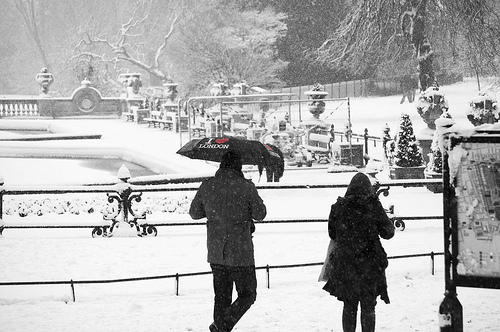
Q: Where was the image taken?
A: It was taken at the park.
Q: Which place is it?
A: It is a park.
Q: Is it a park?
A: Yes, it is a park.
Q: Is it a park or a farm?
A: It is a park.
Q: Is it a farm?
A: No, it is a park.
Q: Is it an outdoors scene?
A: Yes, it is outdoors.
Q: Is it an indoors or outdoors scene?
A: It is outdoors.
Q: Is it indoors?
A: No, it is outdoors.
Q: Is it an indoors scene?
A: No, it is outdoors.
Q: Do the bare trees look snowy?
A: Yes, the trees are snowy.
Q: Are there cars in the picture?
A: No, there are no cars.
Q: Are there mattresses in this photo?
A: No, there are no mattresses.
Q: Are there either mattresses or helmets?
A: No, there are no mattresses or helmets.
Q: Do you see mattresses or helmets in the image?
A: No, there are no mattresses or helmets.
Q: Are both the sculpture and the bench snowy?
A: Yes, both the sculpture and the bench are snowy.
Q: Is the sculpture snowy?
A: Yes, the sculpture is snowy.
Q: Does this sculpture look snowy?
A: Yes, the sculpture is snowy.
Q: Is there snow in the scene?
A: Yes, there is snow.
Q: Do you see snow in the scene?
A: Yes, there is snow.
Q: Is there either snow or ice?
A: Yes, there is snow.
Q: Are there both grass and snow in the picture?
A: No, there is snow but no grass.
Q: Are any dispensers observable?
A: No, there are no dispensers.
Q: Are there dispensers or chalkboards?
A: No, there are no dispensers or chalkboards.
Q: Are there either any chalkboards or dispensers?
A: No, there are no dispensers or chalkboards.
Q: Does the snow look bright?
A: Yes, the snow is bright.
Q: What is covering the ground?
A: The snow is covering the ground.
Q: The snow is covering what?
A: The snow is covering the ground.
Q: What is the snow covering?
A: The snow is covering the ground.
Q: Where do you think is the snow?
A: The snow is on the ground.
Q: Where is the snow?
A: The snow is on the ground.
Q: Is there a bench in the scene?
A: Yes, there is a bench.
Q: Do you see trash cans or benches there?
A: Yes, there is a bench.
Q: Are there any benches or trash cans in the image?
A: Yes, there is a bench.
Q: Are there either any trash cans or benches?
A: Yes, there is a bench.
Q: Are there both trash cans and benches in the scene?
A: No, there is a bench but no trash cans.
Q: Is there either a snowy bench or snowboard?
A: Yes, there is a snowy bench.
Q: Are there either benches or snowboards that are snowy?
A: Yes, the bench is snowy.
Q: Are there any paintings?
A: No, there are no paintings.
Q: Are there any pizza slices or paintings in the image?
A: No, there are no paintings or pizza slices.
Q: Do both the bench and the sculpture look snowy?
A: Yes, both the bench and the sculpture are snowy.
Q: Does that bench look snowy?
A: Yes, the bench is snowy.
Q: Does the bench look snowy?
A: Yes, the bench is snowy.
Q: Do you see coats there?
A: Yes, there is a coat.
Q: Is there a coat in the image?
A: Yes, there is a coat.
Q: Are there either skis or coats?
A: Yes, there is a coat.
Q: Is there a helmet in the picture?
A: No, there are no helmets.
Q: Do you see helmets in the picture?
A: No, there are no helmets.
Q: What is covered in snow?
A: The ground is covered in snow.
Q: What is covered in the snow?
A: The ground is covered in snow.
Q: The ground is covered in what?
A: The ground is covered in snow.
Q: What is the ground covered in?
A: The ground is covered in snow.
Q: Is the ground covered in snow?
A: Yes, the ground is covered in snow.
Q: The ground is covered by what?
A: The ground is covered by the snow.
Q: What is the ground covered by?
A: The ground is covered by the snow.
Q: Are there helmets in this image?
A: No, there are no helmets.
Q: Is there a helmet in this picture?
A: No, there are no helmets.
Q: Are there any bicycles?
A: No, there are no bicycles.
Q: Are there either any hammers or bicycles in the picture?
A: No, there are no bicycles or hammers.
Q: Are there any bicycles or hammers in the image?
A: No, there are no bicycles or hammers.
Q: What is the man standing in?
A: The man is standing in the snow.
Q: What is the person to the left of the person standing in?
A: The man is standing in the snow.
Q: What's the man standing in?
A: The man is standing in the snow.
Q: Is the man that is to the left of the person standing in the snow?
A: Yes, the man is standing in the snow.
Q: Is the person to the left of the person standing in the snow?
A: Yes, the man is standing in the snow.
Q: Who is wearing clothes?
A: The man is wearing clothes.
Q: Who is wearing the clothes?
A: The man is wearing clothes.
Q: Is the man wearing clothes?
A: Yes, the man is wearing clothes.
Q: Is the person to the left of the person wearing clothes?
A: Yes, the man is wearing clothes.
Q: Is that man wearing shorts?
A: No, the man is wearing clothes.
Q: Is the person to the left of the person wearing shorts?
A: No, the man is wearing clothes.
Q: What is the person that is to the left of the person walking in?
A: The man is walking in the snow.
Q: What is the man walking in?
A: The man is walking in the snow.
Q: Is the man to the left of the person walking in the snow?
A: Yes, the man is walking in the snow.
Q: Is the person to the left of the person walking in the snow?
A: Yes, the man is walking in the snow.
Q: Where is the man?
A: The man is in the snow.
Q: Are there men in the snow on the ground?
A: Yes, there is a man in the snow.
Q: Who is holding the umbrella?
A: The man is holding the umbrella.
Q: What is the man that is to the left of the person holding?
A: The man is holding the umbrella.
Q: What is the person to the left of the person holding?
A: The man is holding the umbrella.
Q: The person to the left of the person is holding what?
A: The man is holding the umbrella.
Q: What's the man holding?
A: The man is holding the umbrella.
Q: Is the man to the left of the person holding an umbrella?
A: Yes, the man is holding an umbrella.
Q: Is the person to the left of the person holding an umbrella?
A: Yes, the man is holding an umbrella.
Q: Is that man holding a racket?
A: No, the man is holding an umbrella.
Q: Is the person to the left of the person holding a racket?
A: No, the man is holding an umbrella.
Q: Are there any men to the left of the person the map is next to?
A: Yes, there is a man to the left of the person.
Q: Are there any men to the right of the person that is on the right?
A: No, the man is to the left of the person.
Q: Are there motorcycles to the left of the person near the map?
A: No, there is a man to the left of the person.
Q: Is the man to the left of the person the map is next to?
A: Yes, the man is to the left of the person.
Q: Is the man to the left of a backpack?
A: No, the man is to the left of the person.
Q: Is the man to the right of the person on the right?
A: No, the man is to the left of the person.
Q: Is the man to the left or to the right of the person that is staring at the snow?
A: The man is to the left of the person.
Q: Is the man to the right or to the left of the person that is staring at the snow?
A: The man is to the left of the person.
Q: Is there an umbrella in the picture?
A: Yes, there is an umbrella.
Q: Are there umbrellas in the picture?
A: Yes, there is an umbrella.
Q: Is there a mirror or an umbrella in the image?
A: Yes, there is an umbrella.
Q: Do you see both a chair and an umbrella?
A: No, there is an umbrella but no chairs.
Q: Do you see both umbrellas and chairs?
A: No, there is an umbrella but no chairs.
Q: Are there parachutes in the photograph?
A: No, there are no parachutes.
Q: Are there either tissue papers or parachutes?
A: No, there are no parachutes or tissue papers.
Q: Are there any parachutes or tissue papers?
A: No, there are no parachutes or tissue papers.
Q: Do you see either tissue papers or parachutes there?
A: No, there are no parachutes or tissue papers.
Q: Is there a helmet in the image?
A: No, there are no helmets.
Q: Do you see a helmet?
A: No, there are no helmets.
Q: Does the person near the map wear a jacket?
A: Yes, the person wears a jacket.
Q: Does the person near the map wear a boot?
A: No, the person wears a jacket.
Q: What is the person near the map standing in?
A: The person is standing in the snow.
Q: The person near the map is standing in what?
A: The person is standing in the snow.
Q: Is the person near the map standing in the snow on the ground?
A: Yes, the person is standing in the snow.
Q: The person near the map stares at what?
A: The person stares at the snow.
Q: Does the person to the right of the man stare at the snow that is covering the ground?
A: Yes, the person stares at the snow.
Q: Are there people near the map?
A: Yes, there is a person near the map.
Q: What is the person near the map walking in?
A: The person is walking in the snow.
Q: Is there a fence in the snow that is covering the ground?
A: No, there is a person in the snow.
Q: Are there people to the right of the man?
A: Yes, there is a person to the right of the man.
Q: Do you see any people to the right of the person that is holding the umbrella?
A: Yes, there is a person to the right of the man.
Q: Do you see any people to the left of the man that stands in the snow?
A: No, the person is to the right of the man.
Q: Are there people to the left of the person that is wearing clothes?
A: No, the person is to the right of the man.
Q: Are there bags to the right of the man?
A: No, there is a person to the right of the man.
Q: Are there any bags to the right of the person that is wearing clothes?
A: No, there is a person to the right of the man.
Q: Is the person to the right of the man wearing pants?
A: Yes, the person is wearing pants.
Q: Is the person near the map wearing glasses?
A: No, the person is wearing pants.